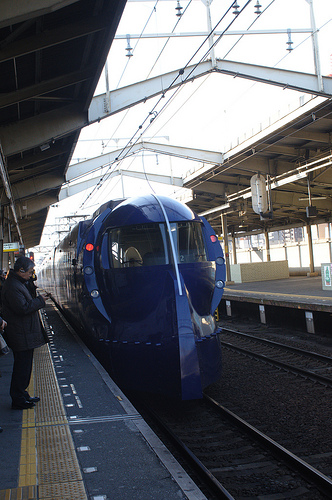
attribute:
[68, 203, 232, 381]
train — blue, stopped, passenger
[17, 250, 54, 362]
man — standing, wearing, looking, waiting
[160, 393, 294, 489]
tracks — center, rail road, stationary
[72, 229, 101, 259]
light — red, round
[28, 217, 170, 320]
system — guiding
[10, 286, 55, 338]
jacket — dark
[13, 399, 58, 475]
markings — yellow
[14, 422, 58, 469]
line — safety, yellow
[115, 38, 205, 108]
wires — black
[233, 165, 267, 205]
sign — white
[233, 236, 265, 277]
wall — tan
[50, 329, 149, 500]
platform — across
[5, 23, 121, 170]
roof — here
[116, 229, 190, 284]
seat — empty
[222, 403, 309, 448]
track — metal